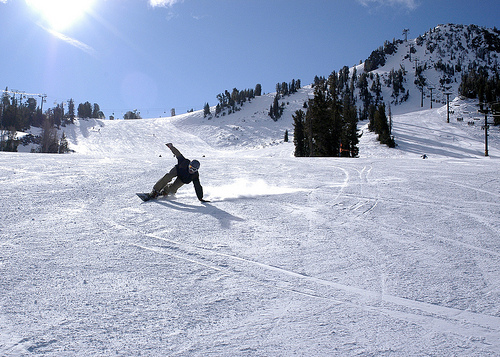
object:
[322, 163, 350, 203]
lines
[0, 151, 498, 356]
slope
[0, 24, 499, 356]
snow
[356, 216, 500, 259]
ski marks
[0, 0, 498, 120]
sky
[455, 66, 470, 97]
trees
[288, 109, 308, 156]
trees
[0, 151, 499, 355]
ground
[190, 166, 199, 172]
goggles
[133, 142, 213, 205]
man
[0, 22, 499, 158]
hill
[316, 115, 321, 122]
leaves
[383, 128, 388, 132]
leaves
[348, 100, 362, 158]
tree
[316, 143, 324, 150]
leaves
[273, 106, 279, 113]
leaves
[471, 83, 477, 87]
leaves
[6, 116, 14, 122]
leaves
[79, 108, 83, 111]
leaves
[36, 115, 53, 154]
tree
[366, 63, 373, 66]
leaves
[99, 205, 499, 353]
tracks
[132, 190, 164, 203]
snowboard